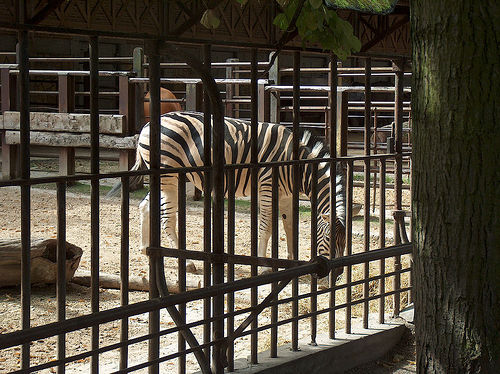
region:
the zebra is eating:
[287, 111, 354, 293]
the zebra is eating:
[287, 140, 394, 352]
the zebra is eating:
[278, 180, 370, 319]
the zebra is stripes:
[87, 82, 394, 371]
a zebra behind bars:
[102, 82, 373, 302]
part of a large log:
[12, 222, 92, 316]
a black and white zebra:
[105, 83, 391, 311]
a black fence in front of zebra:
[47, 15, 434, 354]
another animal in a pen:
[99, 68, 201, 164]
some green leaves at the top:
[252, 6, 379, 69]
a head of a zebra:
[308, 185, 385, 302]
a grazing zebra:
[118, 97, 364, 328]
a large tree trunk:
[399, 16, 496, 372]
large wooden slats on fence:
[3, 100, 148, 164]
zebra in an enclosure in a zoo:
[5, 5, 497, 370]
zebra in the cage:
[135, 111, 362, 293]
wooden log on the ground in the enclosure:
[3, 228, 88, 292]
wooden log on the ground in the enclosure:
[81, 270, 206, 297]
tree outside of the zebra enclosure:
[409, 6, 499, 371]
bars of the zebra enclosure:
[142, 49, 412, 312]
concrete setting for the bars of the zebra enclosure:
[252, 302, 407, 372]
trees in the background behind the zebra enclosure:
[5, 5, 406, 50]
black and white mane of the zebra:
[292, 123, 348, 220]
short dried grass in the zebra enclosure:
[358, 240, 408, 307]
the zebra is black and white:
[103, 108, 368, 285]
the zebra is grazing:
[123, 113, 353, 265]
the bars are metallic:
[21, 98, 406, 312]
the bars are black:
[41, 83, 363, 290]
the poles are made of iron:
[106, 67, 383, 317]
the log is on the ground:
[0, 230, 95, 281]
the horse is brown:
[127, 77, 188, 112]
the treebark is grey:
[418, 151, 493, 301]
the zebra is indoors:
[135, 105, 366, 278]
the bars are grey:
[18, 107, 141, 144]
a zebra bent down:
[109, 88, 349, 285]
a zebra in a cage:
[129, 108, 361, 282]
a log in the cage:
[1, 233, 86, 285]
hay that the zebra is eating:
[330, 245, 412, 315]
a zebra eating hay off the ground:
[113, 110, 409, 310]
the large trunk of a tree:
[408, 15, 498, 371]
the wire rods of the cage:
[8, 26, 414, 366]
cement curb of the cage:
[270, 314, 416, 371]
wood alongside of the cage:
[3, 110, 140, 151]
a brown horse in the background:
[141, 78, 183, 116]